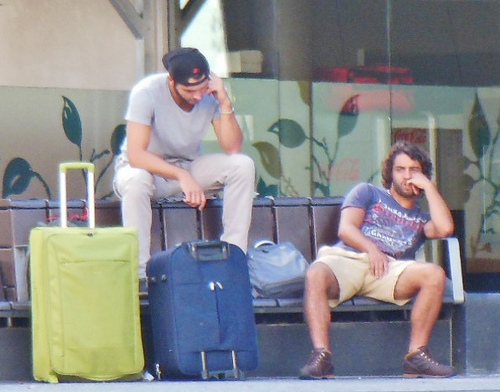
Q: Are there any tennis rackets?
A: No, there are no tennis rackets.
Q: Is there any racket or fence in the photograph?
A: No, there are no rackets or fences.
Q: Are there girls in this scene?
A: No, there are no girls.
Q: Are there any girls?
A: No, there are no girls.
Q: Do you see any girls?
A: No, there are no girls.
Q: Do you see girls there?
A: No, there are no girls.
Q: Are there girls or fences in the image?
A: No, there are no girls or fences.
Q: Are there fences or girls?
A: No, there are no girls or fences.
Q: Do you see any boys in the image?
A: No, there are no boys.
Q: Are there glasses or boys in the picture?
A: No, there are no boys or glasses.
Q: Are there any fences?
A: No, there are no fences.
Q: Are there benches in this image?
A: Yes, there is a bench.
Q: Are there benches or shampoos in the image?
A: Yes, there is a bench.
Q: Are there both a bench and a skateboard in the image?
A: No, there is a bench but no skateboards.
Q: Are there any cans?
A: No, there are no cans.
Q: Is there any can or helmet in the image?
A: No, there are no cans or helmets.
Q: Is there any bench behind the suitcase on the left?
A: Yes, there is a bench behind the suitcase.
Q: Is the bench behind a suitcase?
A: Yes, the bench is behind a suitcase.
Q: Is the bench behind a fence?
A: No, the bench is behind a suitcase.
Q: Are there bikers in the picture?
A: No, there are no bikers.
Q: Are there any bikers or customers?
A: No, there are no bikers or customers.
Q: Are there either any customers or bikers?
A: No, there are no bikers or customers.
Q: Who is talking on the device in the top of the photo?
A: The man is talking on the cell phone.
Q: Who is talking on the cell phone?
A: The man is talking on the cell phone.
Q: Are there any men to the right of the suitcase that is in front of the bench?
A: Yes, there is a man to the right of the suitcase.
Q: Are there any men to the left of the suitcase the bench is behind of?
A: No, the man is to the right of the suitcase.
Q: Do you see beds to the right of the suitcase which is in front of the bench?
A: No, there is a man to the right of the suitcase.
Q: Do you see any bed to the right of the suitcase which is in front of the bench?
A: No, there is a man to the right of the suitcase.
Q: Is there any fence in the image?
A: No, there are no fences.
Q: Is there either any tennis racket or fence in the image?
A: No, there are no fences or rackets.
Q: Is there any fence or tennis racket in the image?
A: No, there are no fences or rackets.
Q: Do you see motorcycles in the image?
A: No, there are no motorcycles.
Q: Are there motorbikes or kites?
A: No, there are no motorbikes or kites.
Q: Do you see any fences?
A: No, there are no fences.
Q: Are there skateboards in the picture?
A: No, there are no skateboards.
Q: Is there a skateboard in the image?
A: No, there are no skateboards.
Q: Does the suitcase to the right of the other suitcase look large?
A: Yes, the suitcase is large.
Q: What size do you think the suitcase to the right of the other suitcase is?
A: The suitcase is large.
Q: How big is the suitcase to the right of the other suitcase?
A: The suitcase is large.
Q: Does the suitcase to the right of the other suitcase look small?
A: No, the suitcase is large.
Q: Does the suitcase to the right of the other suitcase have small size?
A: No, the suitcase is large.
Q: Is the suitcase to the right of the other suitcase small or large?
A: The suitcase is large.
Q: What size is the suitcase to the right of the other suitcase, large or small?
A: The suitcase is large.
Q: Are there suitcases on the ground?
A: Yes, there is a suitcase on the ground.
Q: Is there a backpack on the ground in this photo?
A: No, there is a suitcase on the ground.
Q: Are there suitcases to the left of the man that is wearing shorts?
A: Yes, there is a suitcase to the left of the man.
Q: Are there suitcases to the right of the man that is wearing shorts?
A: No, the suitcase is to the left of the man.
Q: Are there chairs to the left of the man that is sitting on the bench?
A: No, there is a suitcase to the left of the man.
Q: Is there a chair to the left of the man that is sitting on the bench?
A: No, there is a suitcase to the left of the man.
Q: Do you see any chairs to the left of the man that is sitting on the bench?
A: No, there is a suitcase to the left of the man.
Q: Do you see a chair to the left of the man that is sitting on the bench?
A: No, there is a suitcase to the left of the man.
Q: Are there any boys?
A: No, there are no boys.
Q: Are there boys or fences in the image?
A: No, there are no boys or fences.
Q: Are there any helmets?
A: No, there are no helmets.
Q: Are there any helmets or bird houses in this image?
A: No, there are no helmets or bird houses.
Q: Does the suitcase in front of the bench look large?
A: Yes, the suitcase is large.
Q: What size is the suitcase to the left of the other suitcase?
A: The suitcase is large.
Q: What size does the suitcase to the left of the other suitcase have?
A: The suitcase has large size.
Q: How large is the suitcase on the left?
A: The suitcase is large.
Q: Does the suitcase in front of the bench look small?
A: No, the suitcase is large.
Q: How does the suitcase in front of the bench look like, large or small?
A: The suitcase is large.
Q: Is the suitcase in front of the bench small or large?
A: The suitcase is large.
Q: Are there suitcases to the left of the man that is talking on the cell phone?
A: Yes, there is a suitcase to the left of the man.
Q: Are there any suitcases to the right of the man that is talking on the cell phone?
A: No, the suitcase is to the left of the man.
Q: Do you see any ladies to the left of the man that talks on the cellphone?
A: No, there is a suitcase to the left of the man.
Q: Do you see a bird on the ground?
A: No, there is a suitcase on the ground.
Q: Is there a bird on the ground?
A: No, there is a suitcase on the ground.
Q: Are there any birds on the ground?
A: No, there is a suitcase on the ground.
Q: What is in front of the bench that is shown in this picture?
A: The suitcase is in front of the bench.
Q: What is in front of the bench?
A: The suitcase is in front of the bench.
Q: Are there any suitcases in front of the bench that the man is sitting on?
A: Yes, there is a suitcase in front of the bench.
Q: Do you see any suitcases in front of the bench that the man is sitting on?
A: Yes, there is a suitcase in front of the bench.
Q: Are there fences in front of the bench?
A: No, there is a suitcase in front of the bench.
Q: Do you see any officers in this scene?
A: No, there are no officers.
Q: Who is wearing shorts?
A: The man is wearing shorts.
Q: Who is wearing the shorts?
A: The man is wearing shorts.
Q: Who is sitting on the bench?
A: The man is sitting on the bench.